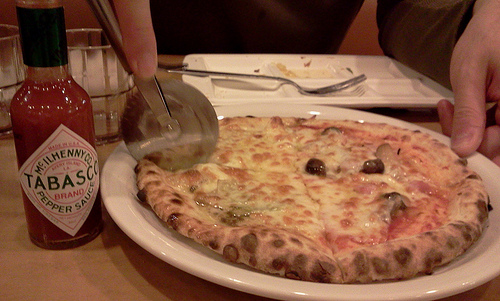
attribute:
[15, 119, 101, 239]
label — diamond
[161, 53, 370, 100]
fork — silver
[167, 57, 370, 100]
fork — dirty, silver, dinner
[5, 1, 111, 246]
sauce — tabasco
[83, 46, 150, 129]
glass — clear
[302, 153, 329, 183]
sausage — small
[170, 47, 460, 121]
plate — empty, dirty, styrofoam, dinner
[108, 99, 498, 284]
plate — round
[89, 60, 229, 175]
cutter — silver, metal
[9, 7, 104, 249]
sauce — hot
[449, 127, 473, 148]
nail — very short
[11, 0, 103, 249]
bottle — glass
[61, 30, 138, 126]
glasses — small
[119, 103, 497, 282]
food — divided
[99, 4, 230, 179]
pizza cutter — silver, round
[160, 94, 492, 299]
pizza — round, cut, baked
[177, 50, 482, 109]
plate — square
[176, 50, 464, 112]
plate — white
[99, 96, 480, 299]
plate — tan